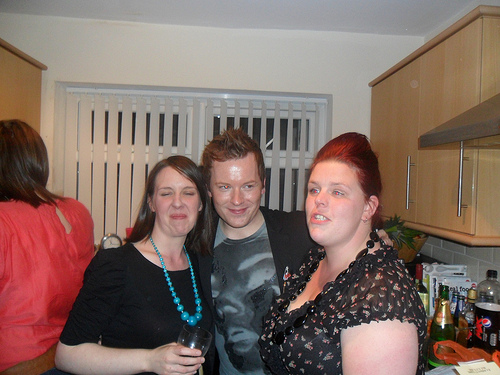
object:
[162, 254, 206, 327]
necklace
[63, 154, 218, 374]
woman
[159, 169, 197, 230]
face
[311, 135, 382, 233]
hair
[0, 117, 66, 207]
hair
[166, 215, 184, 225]
mouth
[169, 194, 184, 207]
nose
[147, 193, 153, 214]
ear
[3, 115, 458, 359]
people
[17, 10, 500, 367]
kitchen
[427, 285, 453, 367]
bottle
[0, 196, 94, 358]
shirt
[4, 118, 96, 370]
woman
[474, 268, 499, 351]
bottle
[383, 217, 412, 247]
plant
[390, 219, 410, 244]
leaf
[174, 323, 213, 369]
glass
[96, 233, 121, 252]
clock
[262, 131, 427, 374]
woman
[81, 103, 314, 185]
blinds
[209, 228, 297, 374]
shirt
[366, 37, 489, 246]
cabinets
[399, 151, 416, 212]
handle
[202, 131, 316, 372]
man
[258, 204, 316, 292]
coat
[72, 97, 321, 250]
window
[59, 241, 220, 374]
dress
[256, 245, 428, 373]
dress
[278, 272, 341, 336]
necklace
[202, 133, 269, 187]
hair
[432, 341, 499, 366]
shopping bag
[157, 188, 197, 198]
eyes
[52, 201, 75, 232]
hole